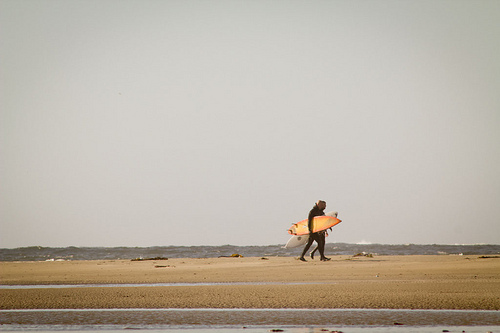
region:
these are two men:
[299, 195, 337, 259]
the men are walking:
[296, 195, 341, 261]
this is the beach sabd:
[358, 261, 420, 308]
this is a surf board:
[314, 215, 334, 230]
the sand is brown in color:
[362, 260, 425, 307]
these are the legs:
[303, 237, 328, 257]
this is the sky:
[61, 36, 313, 193]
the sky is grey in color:
[67, 15, 255, 162]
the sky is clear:
[22, 24, 274, 204]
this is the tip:
[328, 215, 343, 227]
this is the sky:
[115, 34, 254, 126]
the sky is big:
[96, 37, 230, 132]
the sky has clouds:
[124, 64, 211, 185]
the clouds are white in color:
[149, 156, 216, 218]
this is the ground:
[200, 282, 251, 314]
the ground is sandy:
[315, 289, 387, 309]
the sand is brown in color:
[373, 275, 402, 292]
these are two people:
[297, 199, 334, 260]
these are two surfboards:
[290, 217, 342, 233]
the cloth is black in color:
[314, 207, 320, 215]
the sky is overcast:
[55, 98, 230, 200]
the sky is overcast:
[108, 128, 190, 181]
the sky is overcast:
[91, 131, 211, 202]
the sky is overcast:
[120, 115, 231, 206]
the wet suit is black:
[299, 207, 334, 261]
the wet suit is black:
[296, 205, 326, 264]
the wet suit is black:
[297, 199, 339, 278]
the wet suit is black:
[298, 202, 334, 282]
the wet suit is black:
[289, 204, 353, 293]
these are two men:
[296, 195, 340, 255]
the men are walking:
[289, 197, 341, 262]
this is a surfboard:
[314, 213, 334, 228]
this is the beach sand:
[329, 265, 386, 303]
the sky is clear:
[115, 18, 265, 138]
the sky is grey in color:
[107, 30, 279, 171]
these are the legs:
[298, 242, 328, 259]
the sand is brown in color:
[222, 255, 272, 305]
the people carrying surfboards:
[260, 185, 371, 283]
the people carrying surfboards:
[267, 178, 355, 289]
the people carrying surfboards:
[269, 179, 345, 279]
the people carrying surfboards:
[280, 187, 357, 282]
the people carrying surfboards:
[274, 180, 354, 288]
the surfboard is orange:
[288, 214, 343, 239]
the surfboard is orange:
[288, 207, 343, 247]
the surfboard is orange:
[280, 210, 352, 245]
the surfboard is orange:
[283, 207, 358, 249]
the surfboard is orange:
[276, 205, 348, 244]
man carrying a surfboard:
[281, 198, 354, 258]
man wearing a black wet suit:
[295, 202, 341, 258]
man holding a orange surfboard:
[278, 208, 338, 238]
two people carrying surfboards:
[283, 199, 342, 261]